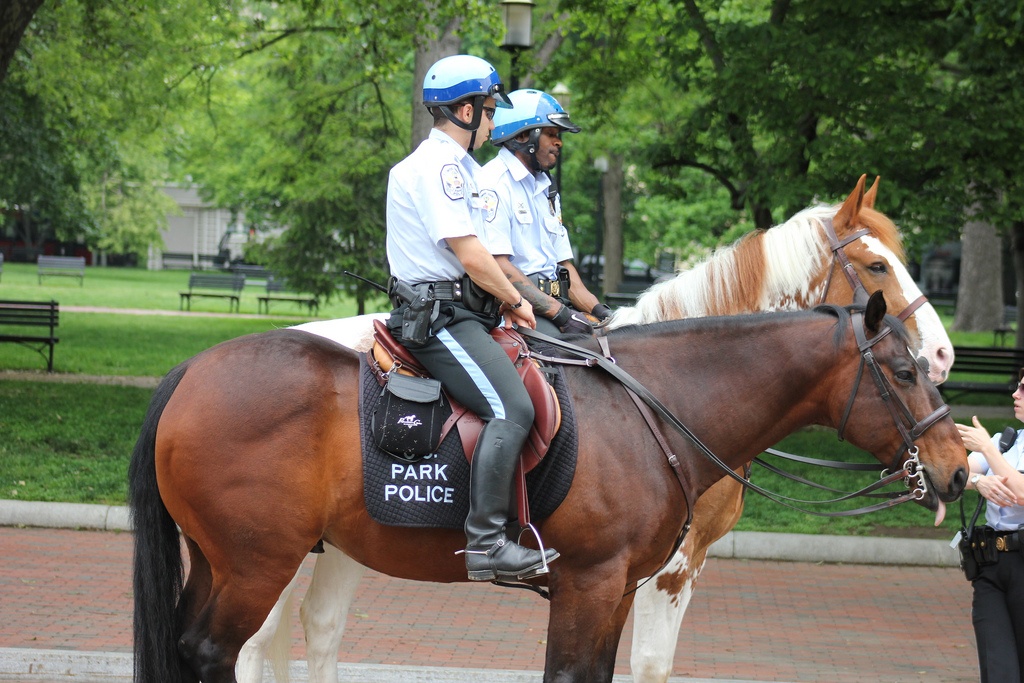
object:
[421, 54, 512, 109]
helmet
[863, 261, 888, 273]
eye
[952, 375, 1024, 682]
woman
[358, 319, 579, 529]
saddle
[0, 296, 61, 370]
bench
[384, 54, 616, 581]
police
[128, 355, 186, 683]
tail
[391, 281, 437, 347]
gun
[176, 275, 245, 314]
bench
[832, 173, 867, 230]
ear.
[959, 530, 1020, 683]
pants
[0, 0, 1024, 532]
park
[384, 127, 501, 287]
uniform shirt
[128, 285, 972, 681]
horse